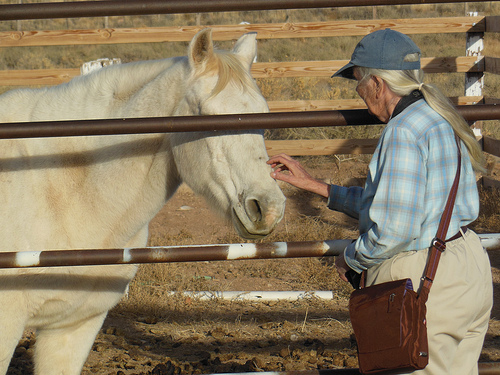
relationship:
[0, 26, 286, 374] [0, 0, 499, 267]
horse behind fence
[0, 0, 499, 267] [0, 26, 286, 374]
fence in front of horse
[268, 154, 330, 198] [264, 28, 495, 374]
right hand of woman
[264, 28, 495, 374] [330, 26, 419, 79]
woman wearing baseball cap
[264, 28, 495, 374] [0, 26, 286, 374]
woman comforting horse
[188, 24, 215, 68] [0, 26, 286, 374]
ear of horse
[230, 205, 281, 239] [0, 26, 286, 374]
jaw of horse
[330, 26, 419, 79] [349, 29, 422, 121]
cap worn on woman's head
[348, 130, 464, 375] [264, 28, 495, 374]
messenger bag hanging off woman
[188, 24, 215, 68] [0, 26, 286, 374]
ear attached onto horse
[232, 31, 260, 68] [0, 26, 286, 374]
ear attached onto horse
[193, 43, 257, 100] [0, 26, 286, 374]
hair attached to horse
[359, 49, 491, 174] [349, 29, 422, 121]
hair attached to woman's head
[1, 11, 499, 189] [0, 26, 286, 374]
fence behind horse